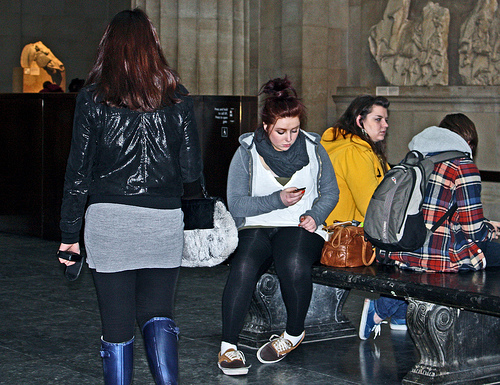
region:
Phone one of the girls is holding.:
[292, 185, 307, 205]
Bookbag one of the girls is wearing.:
[376, 172, 421, 241]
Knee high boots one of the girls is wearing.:
[151, 326, 181, 378]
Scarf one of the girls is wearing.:
[270, 149, 305, 170]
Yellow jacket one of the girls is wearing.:
[346, 142, 365, 174]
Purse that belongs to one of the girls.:
[338, 225, 355, 265]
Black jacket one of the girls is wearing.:
[99, 118, 182, 163]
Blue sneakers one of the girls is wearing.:
[361, 299, 376, 350]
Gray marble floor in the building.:
[30, 276, 61, 348]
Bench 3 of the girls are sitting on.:
[443, 283, 498, 323]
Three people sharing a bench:
[239, 70, 490, 297]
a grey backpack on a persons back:
[361, 150, 469, 252]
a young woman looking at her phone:
[236, 67, 315, 213]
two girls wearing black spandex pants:
[56, 7, 331, 362]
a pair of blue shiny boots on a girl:
[90, 309, 190, 383]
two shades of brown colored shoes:
[210, 325, 312, 381]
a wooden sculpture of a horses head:
[17, 37, 63, 89]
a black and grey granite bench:
[218, 233, 498, 380]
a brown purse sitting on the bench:
[323, 212, 382, 280]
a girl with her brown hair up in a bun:
[246, 70, 317, 167]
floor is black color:
[16, 293, 105, 350]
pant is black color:
[123, 270, 167, 325]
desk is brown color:
[10, 123, 51, 159]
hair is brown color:
[113, 40, 150, 82]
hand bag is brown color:
[326, 228, 369, 255]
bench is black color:
[381, 272, 448, 294]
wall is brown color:
[256, 26, 320, 61]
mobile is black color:
[295, 183, 309, 193]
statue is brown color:
[18, 43, 58, 85]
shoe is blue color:
[359, 300, 378, 344]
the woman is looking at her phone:
[258, 173, 320, 232]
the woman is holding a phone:
[217, 76, 342, 299]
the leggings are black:
[87, 258, 201, 344]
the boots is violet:
[77, 305, 189, 375]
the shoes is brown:
[201, 319, 322, 379]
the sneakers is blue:
[349, 288, 386, 349]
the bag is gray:
[375, 124, 447, 257]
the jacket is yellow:
[321, 113, 393, 236]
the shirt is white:
[214, 121, 362, 244]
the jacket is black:
[77, 82, 207, 237]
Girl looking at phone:
[210, 74, 342, 379]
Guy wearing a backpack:
[360, 110, 499, 277]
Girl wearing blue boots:
[89, 306, 184, 383]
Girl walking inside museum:
[46, 5, 241, 383]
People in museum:
[0, 0, 496, 381]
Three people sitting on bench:
[217, 72, 497, 382]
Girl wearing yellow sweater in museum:
[308, 86, 400, 227]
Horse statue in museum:
[13, 33, 83, 98]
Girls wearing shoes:
[215, 281, 426, 377]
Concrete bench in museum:
[235, 249, 499, 384]